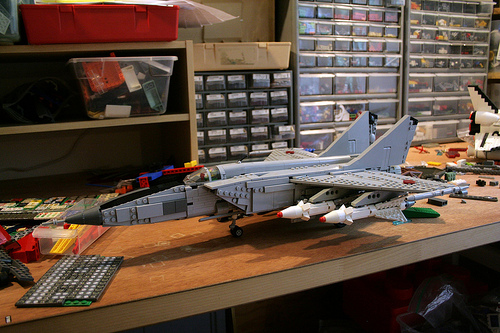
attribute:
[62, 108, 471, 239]
plane — lego, fighter jet, large, jet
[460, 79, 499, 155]
tail — plastic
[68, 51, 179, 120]
box — full, plastic, transparent, clear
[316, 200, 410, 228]
missle — white, lego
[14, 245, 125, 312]
lego — large, grey, gray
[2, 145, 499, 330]
table — long, bench, wood, brown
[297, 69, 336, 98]
bin — full, numerous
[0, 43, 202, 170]
shelf — organized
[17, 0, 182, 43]
container — red, beige, manila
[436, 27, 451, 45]
drawer — small, little